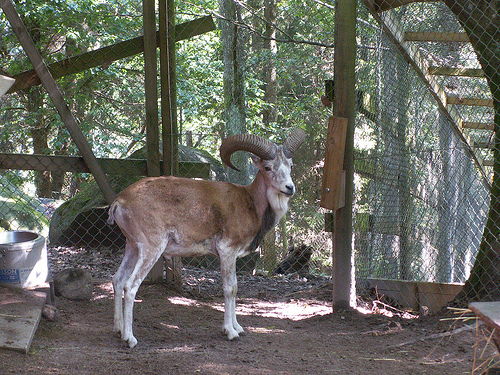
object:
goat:
[105, 128, 293, 348]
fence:
[8, 12, 157, 148]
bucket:
[0, 228, 43, 304]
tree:
[214, 3, 254, 191]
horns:
[216, 119, 269, 173]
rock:
[54, 133, 216, 245]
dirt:
[324, 321, 405, 375]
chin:
[271, 194, 296, 198]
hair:
[262, 198, 292, 220]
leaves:
[95, 76, 112, 93]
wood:
[142, 58, 160, 174]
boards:
[0, 149, 203, 177]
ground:
[44, 345, 210, 375]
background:
[11, 2, 499, 176]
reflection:
[207, 291, 376, 324]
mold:
[54, 147, 117, 202]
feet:
[216, 322, 239, 339]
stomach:
[166, 226, 220, 262]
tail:
[96, 201, 128, 229]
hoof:
[120, 335, 137, 346]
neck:
[241, 177, 266, 212]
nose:
[286, 184, 295, 191]